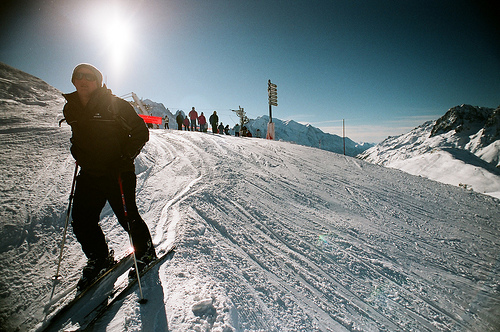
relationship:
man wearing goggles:
[49, 57, 164, 283] [72, 72, 96, 81]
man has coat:
[49, 57, 164, 283] [63, 94, 152, 176]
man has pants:
[49, 57, 164, 283] [70, 159, 155, 256]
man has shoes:
[49, 57, 164, 283] [74, 249, 166, 285]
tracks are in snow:
[174, 138, 248, 220] [174, 141, 491, 297]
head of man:
[70, 60, 110, 102] [49, 57, 164, 283]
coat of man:
[63, 94, 152, 176] [49, 57, 164, 283]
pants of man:
[70, 159, 155, 256] [49, 57, 164, 283]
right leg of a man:
[59, 170, 118, 254] [49, 57, 164, 283]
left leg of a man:
[107, 167, 164, 259] [49, 57, 164, 283]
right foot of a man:
[76, 251, 117, 286] [49, 57, 164, 283]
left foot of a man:
[128, 243, 159, 279] [49, 57, 164, 283]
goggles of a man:
[71, 68, 105, 85] [49, 57, 164, 283]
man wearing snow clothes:
[49, 57, 164, 283] [73, 87, 143, 260]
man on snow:
[49, 57, 164, 283] [174, 141, 491, 297]